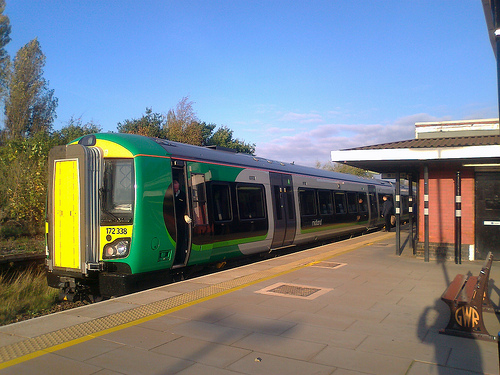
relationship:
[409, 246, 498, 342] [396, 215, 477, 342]
bench at platform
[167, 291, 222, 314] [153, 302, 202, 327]
solid yellow line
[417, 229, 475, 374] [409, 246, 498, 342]
shadow of person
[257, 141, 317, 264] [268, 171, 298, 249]
automatic train automatic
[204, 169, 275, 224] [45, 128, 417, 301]
windows on back of train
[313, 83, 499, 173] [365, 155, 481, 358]
roof on waiting area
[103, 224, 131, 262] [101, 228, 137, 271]
light on back of train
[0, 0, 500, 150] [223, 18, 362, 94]
sky blue sky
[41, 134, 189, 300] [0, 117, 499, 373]
part of at the station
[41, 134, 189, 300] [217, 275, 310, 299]
part a painted line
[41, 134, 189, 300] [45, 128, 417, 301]
part and yellow back of train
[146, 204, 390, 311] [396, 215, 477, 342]
boarding train platform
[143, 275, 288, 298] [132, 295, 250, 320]
long yellow stripe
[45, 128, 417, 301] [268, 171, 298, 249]
back of train exit and entry automatic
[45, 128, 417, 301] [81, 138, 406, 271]
back of train on railroad track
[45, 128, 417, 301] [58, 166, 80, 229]
back of train front yellow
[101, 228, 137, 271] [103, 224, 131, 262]
headlights on train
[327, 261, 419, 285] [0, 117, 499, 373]
open area train at the station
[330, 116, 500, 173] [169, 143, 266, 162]
roof train black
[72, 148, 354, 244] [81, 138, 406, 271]
train color is yellow green and white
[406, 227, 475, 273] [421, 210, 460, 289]
red wall with a black base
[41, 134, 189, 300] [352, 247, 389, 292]
part floor at the station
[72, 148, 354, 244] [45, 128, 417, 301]
parts of back of train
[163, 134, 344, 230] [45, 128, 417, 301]
part of back of train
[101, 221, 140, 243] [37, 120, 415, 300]
number on train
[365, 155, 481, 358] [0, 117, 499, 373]
waiting area on at the station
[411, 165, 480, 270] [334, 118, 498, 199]
poles are supporting roof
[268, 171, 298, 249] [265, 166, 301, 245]
automatic has door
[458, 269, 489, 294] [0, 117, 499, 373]
brown bench on a at the station